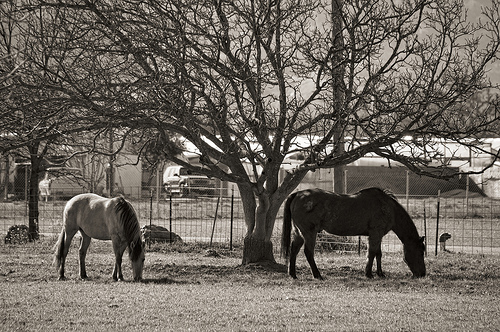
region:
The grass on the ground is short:
[53, 282, 415, 330]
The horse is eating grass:
[35, 193, 165, 285]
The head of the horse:
[401, 235, 432, 280]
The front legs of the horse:
[360, 230, 390, 281]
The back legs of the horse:
[283, 233, 326, 280]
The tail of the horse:
[277, 188, 299, 264]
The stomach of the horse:
[326, 191, 368, 236]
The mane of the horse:
[111, 190, 144, 265]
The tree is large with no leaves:
[31, 15, 497, 119]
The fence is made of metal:
[140, 185, 235, 255]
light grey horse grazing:
[48, 191, 147, 283]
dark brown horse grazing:
[277, 188, 429, 284]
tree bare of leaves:
[8, 5, 498, 269]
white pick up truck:
[39, 164, 89, 202]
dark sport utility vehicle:
[159, 165, 219, 196]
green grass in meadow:
[10, 241, 497, 330]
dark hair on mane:
[116, 193, 142, 260]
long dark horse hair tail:
[278, 190, 297, 257]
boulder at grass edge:
[137, 220, 181, 249]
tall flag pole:
[325, 3, 353, 199]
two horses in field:
[26, 177, 426, 282]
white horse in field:
[40, 195, 148, 288]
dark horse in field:
[276, 181, 423, 283]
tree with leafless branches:
[16, 9, 481, 260]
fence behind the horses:
[18, 169, 494, 250]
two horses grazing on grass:
[46, 172, 446, 277]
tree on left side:
[10, 16, 115, 237]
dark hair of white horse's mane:
[118, 188, 144, 259]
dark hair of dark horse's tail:
[276, 196, 298, 254]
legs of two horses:
[53, 243, 385, 280]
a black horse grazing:
[281, 182, 433, 279]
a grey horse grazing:
[53, 190, 148, 282]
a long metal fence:
[5, 188, 497, 261]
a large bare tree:
[0, 0, 495, 276]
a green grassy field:
[8, 240, 499, 330]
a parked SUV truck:
[162, 163, 215, 193]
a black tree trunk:
[27, 152, 42, 241]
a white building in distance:
[171, 133, 499, 198]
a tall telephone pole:
[332, 1, 344, 189]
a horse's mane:
[113, 195, 139, 257]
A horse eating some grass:
[281, 182, 431, 279]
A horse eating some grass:
[50, 191, 148, 283]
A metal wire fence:
[1, 183, 499, 254]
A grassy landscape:
[1, 233, 497, 330]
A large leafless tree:
[0, 0, 499, 270]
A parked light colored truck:
[36, 166, 91, 203]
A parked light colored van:
[160, 163, 215, 198]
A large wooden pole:
[328, 0, 346, 193]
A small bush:
[4, 219, 35, 247]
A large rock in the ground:
[140, 220, 180, 247]